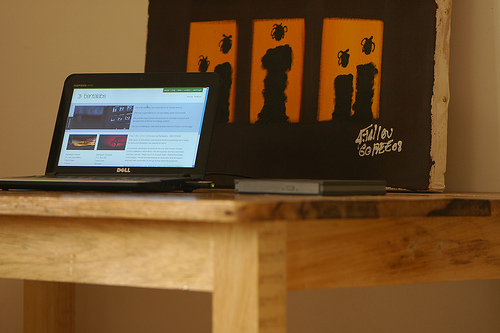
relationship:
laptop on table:
[0, 65, 227, 196] [2, 188, 499, 329]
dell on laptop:
[115, 167, 132, 173] [0, 65, 227, 196]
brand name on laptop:
[110, 164, 135, 176] [0, 65, 227, 196]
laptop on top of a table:
[1, 72, 222, 191] [2, 188, 499, 329]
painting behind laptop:
[140, 2, 444, 192] [1, 56, 215, 221]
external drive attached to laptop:
[236, 171, 398, 204] [0, 65, 227, 196]